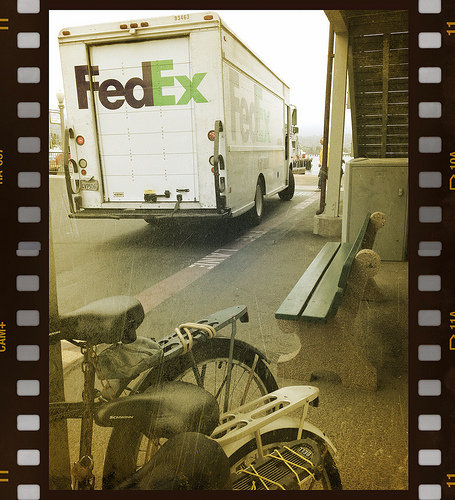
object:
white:
[114, 126, 183, 174]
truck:
[56, 15, 302, 230]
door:
[85, 34, 200, 203]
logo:
[72, 59, 206, 114]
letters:
[74, 59, 209, 109]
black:
[77, 76, 84, 97]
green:
[313, 296, 325, 310]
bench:
[274, 209, 386, 391]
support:
[276, 345, 378, 391]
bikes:
[49, 290, 345, 488]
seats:
[65, 295, 227, 492]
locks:
[174, 323, 210, 354]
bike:
[49, 295, 279, 390]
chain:
[77, 345, 98, 411]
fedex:
[225, 67, 281, 162]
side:
[219, 21, 295, 219]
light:
[68, 129, 224, 152]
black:
[147, 402, 170, 416]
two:
[62, 302, 131, 443]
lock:
[70, 460, 99, 483]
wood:
[290, 290, 330, 311]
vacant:
[281, 232, 331, 358]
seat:
[302, 257, 339, 301]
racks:
[150, 304, 317, 443]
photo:
[47, 11, 414, 493]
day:
[47, 11, 410, 493]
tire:
[248, 173, 269, 229]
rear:
[76, 196, 258, 243]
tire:
[275, 173, 296, 203]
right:
[281, 161, 298, 208]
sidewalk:
[257, 240, 280, 307]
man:
[320, 128, 327, 175]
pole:
[316, 34, 334, 217]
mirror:
[289, 108, 298, 146]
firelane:
[185, 227, 268, 273]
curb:
[131, 221, 297, 269]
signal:
[204, 127, 219, 171]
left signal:
[72, 129, 89, 150]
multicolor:
[74, 86, 202, 100]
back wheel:
[119, 174, 263, 225]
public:
[271, 203, 393, 374]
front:
[272, 77, 303, 196]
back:
[354, 22, 409, 158]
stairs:
[352, 30, 412, 49]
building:
[313, 10, 415, 263]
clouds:
[262, 21, 320, 60]